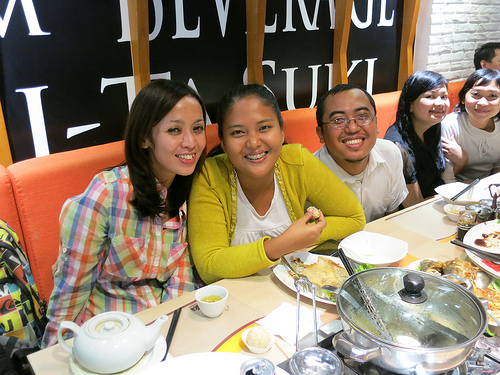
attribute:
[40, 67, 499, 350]
people — smiling, eating together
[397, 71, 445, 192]
hair — long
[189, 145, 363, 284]
sweater — yellow, lime green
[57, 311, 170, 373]
tea kettle — white, porcelain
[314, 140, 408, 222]
shirt — white, button down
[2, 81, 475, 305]
seating — orange, leather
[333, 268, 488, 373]
pot — silver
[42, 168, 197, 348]
shirt — checkered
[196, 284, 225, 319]
cup — yellow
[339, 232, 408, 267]
plate — empty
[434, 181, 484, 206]
bowl — white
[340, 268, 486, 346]
lid — glass, condensed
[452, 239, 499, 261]
tongs — stainless steel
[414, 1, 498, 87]
wall — white